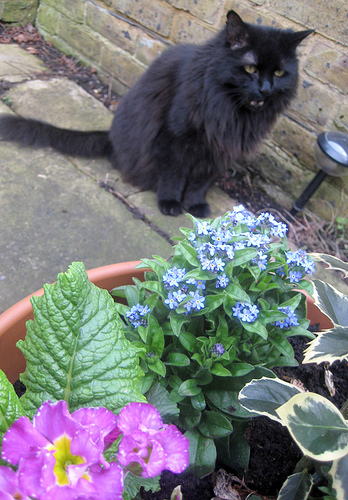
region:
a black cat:
[1, 9, 315, 218]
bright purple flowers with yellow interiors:
[0, 399, 196, 497]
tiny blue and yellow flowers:
[126, 202, 314, 362]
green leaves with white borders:
[236, 249, 347, 496]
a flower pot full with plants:
[0, 254, 345, 496]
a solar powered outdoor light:
[275, 129, 346, 225]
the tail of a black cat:
[0, 108, 115, 160]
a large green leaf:
[12, 259, 150, 412]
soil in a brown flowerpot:
[240, 322, 345, 497]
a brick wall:
[0, 1, 346, 225]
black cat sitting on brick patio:
[1, 6, 314, 216]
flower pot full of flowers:
[0, 253, 338, 476]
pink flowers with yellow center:
[4, 399, 188, 496]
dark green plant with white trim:
[234, 374, 341, 462]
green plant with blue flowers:
[110, 200, 305, 391]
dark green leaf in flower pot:
[12, 256, 144, 403]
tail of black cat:
[0, 108, 110, 157]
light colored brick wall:
[35, 2, 344, 223]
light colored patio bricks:
[1, 44, 245, 322]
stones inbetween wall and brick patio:
[0, 16, 310, 230]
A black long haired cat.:
[114, 9, 310, 215]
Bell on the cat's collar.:
[246, 99, 270, 110]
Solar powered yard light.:
[294, 128, 347, 229]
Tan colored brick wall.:
[46, 3, 166, 46]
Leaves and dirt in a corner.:
[5, 23, 51, 56]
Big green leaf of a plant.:
[23, 262, 137, 398]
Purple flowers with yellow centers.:
[3, 398, 181, 496]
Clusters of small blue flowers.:
[144, 206, 309, 341]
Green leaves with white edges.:
[237, 374, 347, 442]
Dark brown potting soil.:
[248, 424, 284, 490]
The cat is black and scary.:
[124, 18, 294, 193]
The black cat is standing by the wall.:
[108, 11, 327, 241]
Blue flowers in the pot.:
[180, 249, 304, 353]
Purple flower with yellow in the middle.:
[25, 419, 153, 495]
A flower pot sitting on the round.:
[17, 294, 322, 495]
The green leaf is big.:
[27, 295, 143, 423]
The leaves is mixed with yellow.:
[249, 374, 344, 468]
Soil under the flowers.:
[226, 427, 300, 490]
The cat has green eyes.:
[238, 54, 302, 76]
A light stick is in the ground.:
[322, 121, 344, 240]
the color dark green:
[64, 323, 80, 342]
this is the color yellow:
[65, 447, 70, 454]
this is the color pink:
[171, 445, 180, 457]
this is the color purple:
[52, 407, 59, 417]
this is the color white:
[282, 407, 287, 412]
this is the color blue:
[216, 346, 224, 349]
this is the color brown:
[3, 318, 15, 329]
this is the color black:
[253, 444, 264, 453]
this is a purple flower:
[108, 397, 199, 472]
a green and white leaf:
[271, 386, 347, 453]